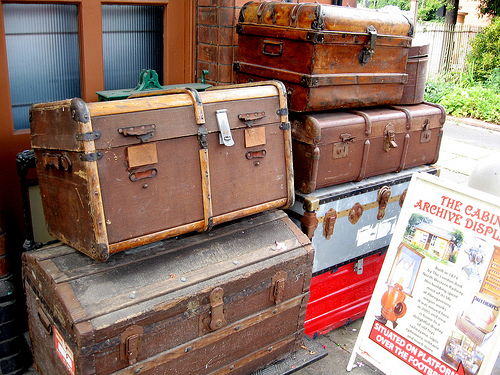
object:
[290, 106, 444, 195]
suitcases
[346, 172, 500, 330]
sign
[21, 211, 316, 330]
suitcase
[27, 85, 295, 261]
suitcase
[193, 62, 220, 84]
brick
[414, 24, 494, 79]
fence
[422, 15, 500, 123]
plants